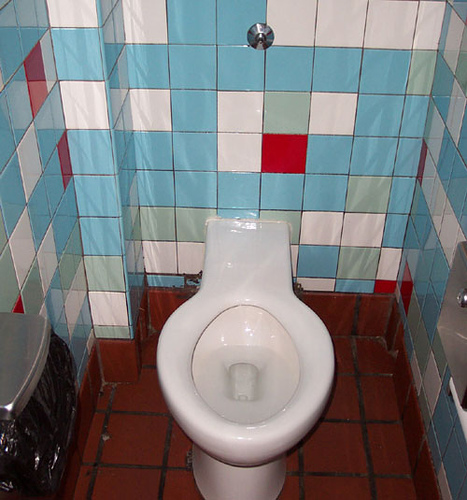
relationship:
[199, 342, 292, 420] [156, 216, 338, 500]
water in toilet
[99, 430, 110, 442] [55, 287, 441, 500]
litter on tiles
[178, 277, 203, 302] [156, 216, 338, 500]
residue behind toilet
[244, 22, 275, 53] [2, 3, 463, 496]
button on wall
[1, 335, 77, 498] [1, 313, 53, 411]
bag in can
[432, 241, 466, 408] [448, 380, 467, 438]
container has paper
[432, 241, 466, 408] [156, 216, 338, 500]
container beside toilet